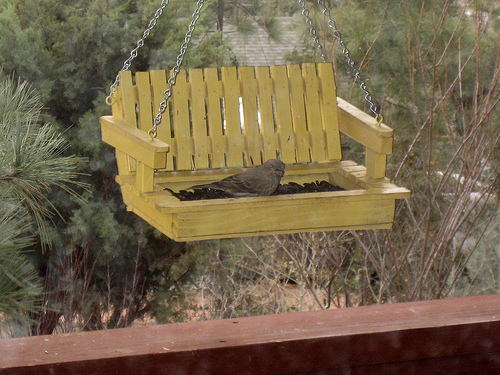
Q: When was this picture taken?
A: During the day.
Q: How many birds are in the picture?
A: One.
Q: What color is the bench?
A: Yellow.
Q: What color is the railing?
A: Red.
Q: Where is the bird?
A: On the bench.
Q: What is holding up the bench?
A: Chains.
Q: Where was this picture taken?
A: A porch.